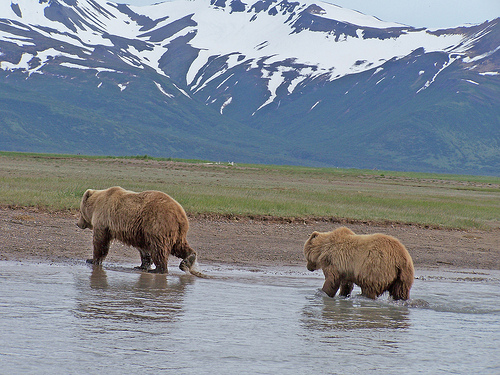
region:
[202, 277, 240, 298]
part of a water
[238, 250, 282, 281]
edge of a shore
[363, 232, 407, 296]
back of a bear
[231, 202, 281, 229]
edge of a field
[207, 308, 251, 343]
part of a water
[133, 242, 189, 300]
;part f a leg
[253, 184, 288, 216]
part of a field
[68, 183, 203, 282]
A large brown bear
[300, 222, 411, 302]
A large brown bear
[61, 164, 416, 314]
A pair of brown bears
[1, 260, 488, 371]
A small body of water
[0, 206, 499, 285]
A dirt shore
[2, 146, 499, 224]
A grassy landscape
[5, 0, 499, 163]
A snow covered mountain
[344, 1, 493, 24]
A blue sky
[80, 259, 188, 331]
reflection of the bear in the water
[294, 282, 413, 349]
reflection of the bear in the water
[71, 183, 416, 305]
two brown bears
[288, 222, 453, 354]
bear walking in the water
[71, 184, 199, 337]
reflection of bear in the water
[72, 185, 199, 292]
back right leg lifted out of the water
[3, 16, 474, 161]
mountains in the background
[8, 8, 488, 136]
snow covered mountain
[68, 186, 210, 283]
bottom of bears belly is wet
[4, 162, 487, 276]
grass beyond the shore of the water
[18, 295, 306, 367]
water is calm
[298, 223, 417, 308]
bear facing downward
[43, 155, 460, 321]
Two bears are walking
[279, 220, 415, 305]
The bear is inside the water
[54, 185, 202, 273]
The bear is walking out of the water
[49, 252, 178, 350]
Reflection of bear in the water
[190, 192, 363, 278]
Bank is not covered in grass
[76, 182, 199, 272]
The bear is very fluffy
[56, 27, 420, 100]
The mountain is covered in snow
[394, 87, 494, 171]
Mountain has lots of grass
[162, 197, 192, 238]
Bear has a short tail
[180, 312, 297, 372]
The water is calm no waves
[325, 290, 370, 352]
part of a water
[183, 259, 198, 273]
edge of a sole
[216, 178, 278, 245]
edge of a field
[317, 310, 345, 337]
part of a shade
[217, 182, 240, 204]
part of a shade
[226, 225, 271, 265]
part of a ground